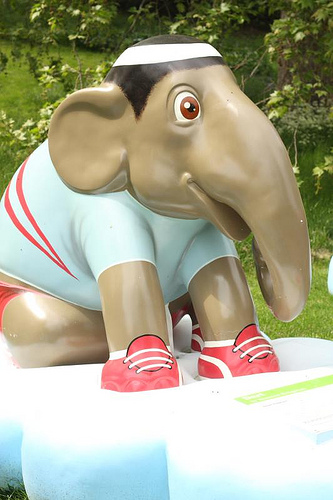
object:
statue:
[0, 33, 313, 394]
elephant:
[0, 34, 312, 392]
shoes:
[100, 334, 182, 393]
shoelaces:
[124, 347, 174, 373]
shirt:
[0, 135, 242, 311]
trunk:
[193, 85, 312, 323]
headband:
[112, 42, 222, 67]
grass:
[0, 33, 312, 394]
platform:
[0, 336, 333, 500]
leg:
[80, 207, 182, 393]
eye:
[174, 91, 202, 121]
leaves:
[28, 0, 47, 24]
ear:
[47, 86, 126, 191]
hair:
[103, 34, 229, 117]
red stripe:
[3, 157, 79, 281]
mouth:
[186, 174, 251, 241]